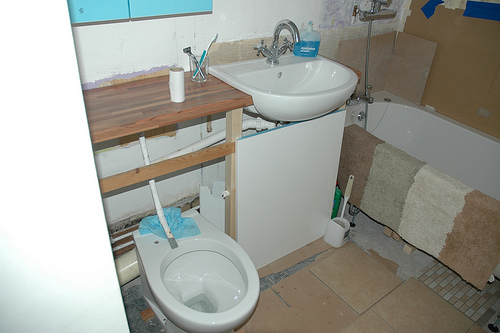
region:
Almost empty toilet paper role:
[165, 65, 188, 103]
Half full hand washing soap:
[295, 20, 320, 60]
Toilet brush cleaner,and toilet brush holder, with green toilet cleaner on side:
[326, 172, 359, 249]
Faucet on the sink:
[255, 18, 301, 60]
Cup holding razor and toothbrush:
[180, 29, 220, 81]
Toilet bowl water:
[179, 290, 214, 316]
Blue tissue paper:
[145, 204, 197, 241]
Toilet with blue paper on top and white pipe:
[140, 210, 260, 325]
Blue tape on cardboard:
[415, 1, 499, 18]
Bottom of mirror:
[70, 0, 211, 24]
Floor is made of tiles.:
[280, 255, 416, 325]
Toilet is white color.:
[136, 210, 261, 320]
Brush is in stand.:
[180, 20, 220, 77]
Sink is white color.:
[206, 35, 351, 110]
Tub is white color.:
[350, 85, 495, 207]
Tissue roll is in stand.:
[160, 50, 195, 130]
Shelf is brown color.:
[80, 65, 245, 125]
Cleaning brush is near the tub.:
[322, 165, 362, 256]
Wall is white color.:
[85, 28, 215, 199]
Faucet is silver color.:
[259, 13, 305, 64]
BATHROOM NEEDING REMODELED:
[80, 3, 499, 320]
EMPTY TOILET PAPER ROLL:
[143, 54, 208, 112]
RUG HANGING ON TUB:
[342, 115, 499, 276]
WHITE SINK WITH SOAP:
[222, 9, 354, 149]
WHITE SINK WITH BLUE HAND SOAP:
[225, 8, 373, 154]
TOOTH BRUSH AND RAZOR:
[181, 20, 260, 124]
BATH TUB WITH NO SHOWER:
[324, 0, 497, 325]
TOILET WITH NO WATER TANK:
[103, 90, 259, 332]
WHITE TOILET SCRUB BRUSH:
[325, 158, 395, 327]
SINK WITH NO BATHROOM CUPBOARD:
[191, 11, 373, 301]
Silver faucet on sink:
[239, 13, 329, 89]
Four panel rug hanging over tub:
[328, 103, 499, 296]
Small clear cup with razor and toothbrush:
[184, 26, 226, 93]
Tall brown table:
[79, 50, 248, 274]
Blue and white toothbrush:
[192, 25, 222, 80]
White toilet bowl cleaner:
[319, 164, 369, 257]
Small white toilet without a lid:
[119, 191, 289, 331]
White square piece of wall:
[227, 90, 360, 289]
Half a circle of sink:
[198, 34, 376, 139]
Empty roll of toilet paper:
[151, 63, 196, 108]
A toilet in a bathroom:
[127, 199, 267, 329]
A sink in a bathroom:
[204, 14, 358, 124]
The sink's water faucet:
[267, 16, 302, 68]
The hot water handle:
[249, 40, 272, 62]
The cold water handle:
[280, 34, 295, 59]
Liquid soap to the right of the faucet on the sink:
[290, 18, 322, 62]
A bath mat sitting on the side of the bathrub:
[341, 116, 498, 293]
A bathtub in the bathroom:
[323, 85, 498, 280]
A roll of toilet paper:
[162, 64, 192, 105]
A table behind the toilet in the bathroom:
[79, 62, 255, 294]